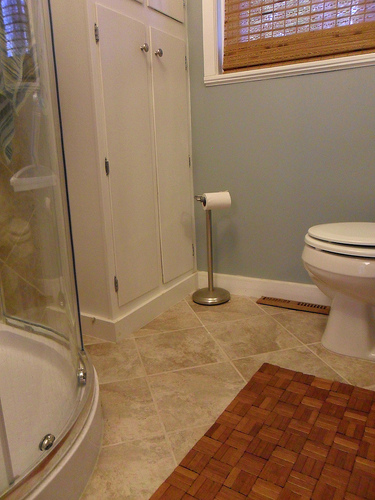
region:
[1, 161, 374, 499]
THERE ARE A BATH ROOM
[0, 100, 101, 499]
THERE ARE A BATH ROOM GLASS SHOWER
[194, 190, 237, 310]
THERE ARE A BATH ROOM TISSUE HOLDER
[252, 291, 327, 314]
THERE ARE A BATH ROOM BROWN VENT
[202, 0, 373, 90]
THERE ARE A BATH ROOM UPPER WINDOW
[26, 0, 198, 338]
THERE ARE A BATH ROOM COSET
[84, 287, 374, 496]
THERE ARE A BATH ROOM VINAL RUG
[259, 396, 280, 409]
wood piece on floor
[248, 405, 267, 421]
wood piece on floor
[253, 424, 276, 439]
wood piece on floor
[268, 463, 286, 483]
wood piece on floor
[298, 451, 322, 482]
wood piece on floor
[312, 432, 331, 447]
wood piece on floor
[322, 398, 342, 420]
wood piece on floor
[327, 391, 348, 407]
wood piece on floor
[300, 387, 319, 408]
wood piece on floor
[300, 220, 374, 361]
A white toilet.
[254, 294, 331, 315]
A brown wooden floor vent.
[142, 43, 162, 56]
Two silver knobs on two white cabinets.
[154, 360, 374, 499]
A brown woven floor in the bathroom.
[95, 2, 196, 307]
Two bottom white long cabinets in a bathroom.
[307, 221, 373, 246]
A white toilet seat lid.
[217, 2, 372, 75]
A long brown blind on the window.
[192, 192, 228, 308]
A tall silver toilet paper holder.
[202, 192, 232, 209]
White roll of toilet paper.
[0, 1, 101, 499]
A tall glass shower with white ring on the bottom.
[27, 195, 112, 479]
The shower is enclosed in glass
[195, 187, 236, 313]
The toilet paper is on a stand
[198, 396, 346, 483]
A woven bath mat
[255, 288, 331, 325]
The furnace vent next to the wall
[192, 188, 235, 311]
The toilet paper holder is chrome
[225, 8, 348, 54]
The shade on the window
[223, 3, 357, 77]
The shade on the window is brown and woven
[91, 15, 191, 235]
The cabinet where the towels are kept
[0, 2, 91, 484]
A sliding glass door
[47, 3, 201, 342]
some white, wooden cabinets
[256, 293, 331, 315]
A vent on the ground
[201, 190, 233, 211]
a roll of toilet paper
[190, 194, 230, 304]
a metal toilet paper holder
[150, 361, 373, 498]
A large red rug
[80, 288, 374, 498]
A brown tiled floor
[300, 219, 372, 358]
A large white toilet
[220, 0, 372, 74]
some wooden blinds over a window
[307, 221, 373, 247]
A white toilet seat